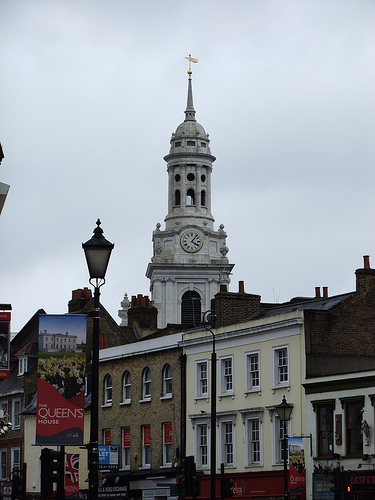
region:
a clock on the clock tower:
[179, 228, 205, 254]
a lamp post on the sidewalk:
[82, 218, 115, 499]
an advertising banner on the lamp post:
[35, 313, 92, 446]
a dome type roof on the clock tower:
[169, 120, 208, 139]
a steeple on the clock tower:
[184, 70, 197, 121]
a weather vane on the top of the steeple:
[185, 53, 200, 76]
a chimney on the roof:
[354, 254, 373, 291]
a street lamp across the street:
[274, 394, 293, 499]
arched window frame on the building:
[140, 364, 152, 402]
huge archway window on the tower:
[176, 280, 207, 326]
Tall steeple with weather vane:
[179, 51, 200, 124]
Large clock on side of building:
[177, 226, 206, 252]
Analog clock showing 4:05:
[178, 230, 206, 256]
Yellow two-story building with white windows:
[221, 335, 272, 470]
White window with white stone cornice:
[237, 403, 263, 469]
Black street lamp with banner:
[33, 219, 113, 496]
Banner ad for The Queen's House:
[31, 309, 93, 449]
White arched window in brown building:
[157, 361, 176, 402]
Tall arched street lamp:
[204, 308, 219, 496]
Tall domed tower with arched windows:
[160, 123, 217, 229]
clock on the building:
[169, 224, 216, 264]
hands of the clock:
[190, 233, 199, 248]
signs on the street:
[285, 433, 309, 499]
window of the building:
[237, 406, 265, 479]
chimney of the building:
[346, 248, 374, 296]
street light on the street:
[76, 223, 111, 492]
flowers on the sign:
[36, 360, 89, 404]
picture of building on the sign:
[28, 324, 83, 357]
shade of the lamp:
[269, 392, 299, 424]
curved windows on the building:
[94, 359, 176, 406]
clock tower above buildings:
[142, 74, 241, 309]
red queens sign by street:
[38, 322, 92, 460]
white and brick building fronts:
[99, 332, 372, 452]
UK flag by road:
[52, 447, 85, 498]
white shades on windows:
[119, 419, 149, 447]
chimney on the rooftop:
[344, 239, 374, 294]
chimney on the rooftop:
[229, 272, 278, 312]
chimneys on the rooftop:
[310, 279, 336, 299]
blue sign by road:
[96, 439, 128, 465]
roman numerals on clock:
[182, 229, 215, 252]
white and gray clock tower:
[137, 32, 263, 316]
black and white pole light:
[77, 213, 116, 498]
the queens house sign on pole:
[35, 371, 96, 456]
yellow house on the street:
[182, 337, 307, 489]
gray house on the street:
[102, 352, 174, 468]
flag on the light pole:
[36, 310, 87, 386]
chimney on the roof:
[216, 282, 275, 327]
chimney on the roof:
[348, 247, 370, 305]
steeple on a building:
[117, 285, 139, 339]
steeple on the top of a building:
[144, 37, 223, 320]